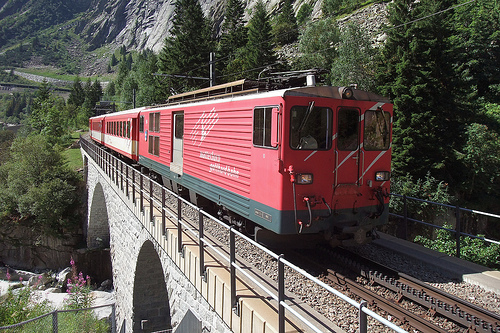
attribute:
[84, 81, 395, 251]
train — red, moving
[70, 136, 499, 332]
bridge — stone, gray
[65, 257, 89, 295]
flowers — purple, pink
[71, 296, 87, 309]
branches — green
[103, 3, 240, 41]
mountains — high, steep, gray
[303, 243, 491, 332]
tracks — metal, set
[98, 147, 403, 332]
railing — metal, gray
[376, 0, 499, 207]
trees — tall, green, pine, leafy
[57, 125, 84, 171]
grass — green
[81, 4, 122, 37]
hillside — rocky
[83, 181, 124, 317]
archway — stone, gray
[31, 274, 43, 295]
flower — pink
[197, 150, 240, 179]
text — white